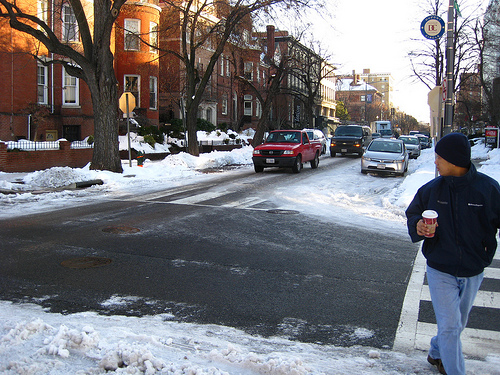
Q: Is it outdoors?
A: Yes, it is outdoors.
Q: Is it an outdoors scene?
A: Yes, it is outdoors.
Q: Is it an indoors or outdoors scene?
A: It is outdoors.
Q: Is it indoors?
A: No, it is outdoors.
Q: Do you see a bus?
A: No, there are no buses.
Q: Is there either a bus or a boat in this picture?
A: No, there are no buses or boats.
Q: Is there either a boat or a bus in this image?
A: No, there are no buses or boats.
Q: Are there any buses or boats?
A: No, there are no buses or boats.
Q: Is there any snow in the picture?
A: Yes, there is snow.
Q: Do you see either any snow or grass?
A: Yes, there is snow.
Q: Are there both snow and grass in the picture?
A: No, there is snow but no grass.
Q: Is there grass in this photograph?
A: No, there is no grass.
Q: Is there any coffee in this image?
A: Yes, there is coffee.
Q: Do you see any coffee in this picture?
A: Yes, there is coffee.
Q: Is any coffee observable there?
A: Yes, there is coffee.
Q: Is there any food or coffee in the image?
A: Yes, there is coffee.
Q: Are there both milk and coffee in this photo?
A: No, there is coffee but no milk.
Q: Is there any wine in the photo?
A: No, there is no wine.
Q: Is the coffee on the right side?
A: Yes, the coffee is on the right of the image.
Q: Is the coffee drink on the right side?
A: Yes, the coffee is on the right of the image.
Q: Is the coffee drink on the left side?
A: No, the coffee is on the right of the image.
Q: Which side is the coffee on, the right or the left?
A: The coffee is on the right of the image.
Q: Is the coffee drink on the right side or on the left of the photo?
A: The coffee is on the right of the image.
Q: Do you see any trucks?
A: Yes, there is a truck.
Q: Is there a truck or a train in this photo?
A: Yes, there is a truck.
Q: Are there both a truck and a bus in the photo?
A: No, there is a truck but no buses.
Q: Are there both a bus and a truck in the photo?
A: No, there is a truck but no buses.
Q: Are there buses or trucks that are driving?
A: Yes, the truck is driving.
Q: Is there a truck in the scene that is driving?
A: Yes, there is a truck that is driving.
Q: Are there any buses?
A: No, there are no buses.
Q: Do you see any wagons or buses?
A: No, there are no buses or wagons.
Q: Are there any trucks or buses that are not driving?
A: No, there is a truck but it is driving.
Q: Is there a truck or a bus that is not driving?
A: No, there is a truck but it is driving.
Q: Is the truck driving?
A: Yes, the truck is driving.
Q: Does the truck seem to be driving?
A: Yes, the truck is driving.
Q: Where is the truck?
A: The truck is on the snow.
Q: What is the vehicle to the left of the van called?
A: The vehicle is a truck.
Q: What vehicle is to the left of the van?
A: The vehicle is a truck.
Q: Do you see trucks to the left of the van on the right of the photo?
A: Yes, there is a truck to the left of the van.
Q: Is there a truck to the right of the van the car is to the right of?
A: No, the truck is to the left of the van.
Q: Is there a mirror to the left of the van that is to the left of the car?
A: No, there is a truck to the left of the van.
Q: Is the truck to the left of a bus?
A: No, the truck is to the left of the van.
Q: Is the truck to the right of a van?
A: No, the truck is to the left of a van.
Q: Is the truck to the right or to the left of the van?
A: The truck is to the left of the van.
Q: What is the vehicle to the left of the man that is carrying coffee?
A: The vehicle is a truck.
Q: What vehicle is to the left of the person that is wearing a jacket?
A: The vehicle is a truck.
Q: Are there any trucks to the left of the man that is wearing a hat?
A: Yes, there is a truck to the left of the man.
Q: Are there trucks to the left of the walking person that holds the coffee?
A: Yes, there is a truck to the left of the man.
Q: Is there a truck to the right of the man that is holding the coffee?
A: No, the truck is to the left of the man.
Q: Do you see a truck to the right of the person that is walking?
A: No, the truck is to the left of the man.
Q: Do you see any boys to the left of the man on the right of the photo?
A: No, there is a truck to the left of the man.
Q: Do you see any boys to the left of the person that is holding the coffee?
A: No, there is a truck to the left of the man.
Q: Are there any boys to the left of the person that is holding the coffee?
A: No, there is a truck to the left of the man.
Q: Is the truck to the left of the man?
A: Yes, the truck is to the left of the man.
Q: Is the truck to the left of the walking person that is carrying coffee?
A: Yes, the truck is to the left of the man.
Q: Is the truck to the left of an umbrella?
A: No, the truck is to the left of the man.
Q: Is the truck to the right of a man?
A: No, the truck is to the left of a man.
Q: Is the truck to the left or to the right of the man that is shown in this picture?
A: The truck is to the left of the man.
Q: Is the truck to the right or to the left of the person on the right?
A: The truck is to the left of the man.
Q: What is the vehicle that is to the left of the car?
A: The vehicle is a truck.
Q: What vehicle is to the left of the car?
A: The vehicle is a truck.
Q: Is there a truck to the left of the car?
A: Yes, there is a truck to the left of the car.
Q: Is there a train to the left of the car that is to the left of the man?
A: No, there is a truck to the left of the car.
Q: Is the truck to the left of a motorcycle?
A: No, the truck is to the left of the car.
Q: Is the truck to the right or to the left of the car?
A: The truck is to the left of the car.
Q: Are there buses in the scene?
A: No, there are no buses.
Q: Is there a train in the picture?
A: No, there are no trains.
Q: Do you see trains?
A: No, there are no trains.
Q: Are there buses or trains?
A: No, there are no trains or buses.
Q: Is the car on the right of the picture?
A: Yes, the car is on the right of the image.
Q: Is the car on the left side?
A: No, the car is on the right of the image.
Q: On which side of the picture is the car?
A: The car is on the right of the image.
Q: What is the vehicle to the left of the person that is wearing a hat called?
A: The vehicle is a car.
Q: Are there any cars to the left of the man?
A: Yes, there is a car to the left of the man.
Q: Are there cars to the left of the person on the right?
A: Yes, there is a car to the left of the man.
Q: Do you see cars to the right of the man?
A: No, the car is to the left of the man.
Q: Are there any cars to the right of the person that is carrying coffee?
A: No, the car is to the left of the man.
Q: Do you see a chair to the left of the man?
A: No, there is a car to the left of the man.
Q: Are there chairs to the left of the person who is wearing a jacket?
A: No, there is a car to the left of the man.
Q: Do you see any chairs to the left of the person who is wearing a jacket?
A: No, there is a car to the left of the man.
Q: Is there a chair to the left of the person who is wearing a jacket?
A: No, there is a car to the left of the man.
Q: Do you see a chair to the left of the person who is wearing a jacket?
A: No, there is a car to the left of the man.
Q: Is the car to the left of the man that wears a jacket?
A: Yes, the car is to the left of the man.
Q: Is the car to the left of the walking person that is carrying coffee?
A: Yes, the car is to the left of the man.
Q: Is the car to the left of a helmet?
A: No, the car is to the left of the man.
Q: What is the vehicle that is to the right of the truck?
A: The vehicle is a car.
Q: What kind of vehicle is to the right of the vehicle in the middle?
A: The vehicle is a car.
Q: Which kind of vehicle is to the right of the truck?
A: The vehicle is a car.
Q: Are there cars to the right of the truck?
A: Yes, there is a car to the right of the truck.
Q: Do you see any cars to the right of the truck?
A: Yes, there is a car to the right of the truck.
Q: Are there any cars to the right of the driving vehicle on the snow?
A: Yes, there is a car to the right of the truck.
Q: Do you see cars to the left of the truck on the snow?
A: No, the car is to the right of the truck.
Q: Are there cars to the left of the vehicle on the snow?
A: No, the car is to the right of the truck.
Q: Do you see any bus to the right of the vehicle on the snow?
A: No, there is a car to the right of the truck.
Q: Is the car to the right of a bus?
A: No, the car is to the right of a truck.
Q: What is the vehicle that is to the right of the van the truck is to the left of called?
A: The vehicle is a car.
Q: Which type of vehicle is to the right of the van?
A: The vehicle is a car.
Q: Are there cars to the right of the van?
A: Yes, there is a car to the right of the van.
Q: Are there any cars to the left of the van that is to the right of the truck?
A: No, the car is to the right of the van.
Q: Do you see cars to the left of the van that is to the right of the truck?
A: No, the car is to the right of the van.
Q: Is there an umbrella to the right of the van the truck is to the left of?
A: No, there is a car to the right of the van.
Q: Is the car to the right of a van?
A: Yes, the car is to the right of a van.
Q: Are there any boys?
A: No, there are no boys.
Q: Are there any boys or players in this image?
A: No, there are no boys or players.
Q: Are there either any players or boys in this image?
A: No, there are no boys or players.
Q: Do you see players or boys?
A: No, there are no boys or players.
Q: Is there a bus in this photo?
A: No, there are no buses.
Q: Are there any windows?
A: Yes, there are windows.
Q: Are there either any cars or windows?
A: Yes, there are windows.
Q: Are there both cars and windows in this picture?
A: Yes, there are both windows and a car.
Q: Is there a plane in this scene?
A: No, there are no airplanes.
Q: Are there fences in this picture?
A: Yes, there is a fence.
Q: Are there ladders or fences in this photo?
A: Yes, there is a fence.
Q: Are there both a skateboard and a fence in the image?
A: No, there is a fence but no skateboards.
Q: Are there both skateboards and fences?
A: No, there is a fence but no skateboards.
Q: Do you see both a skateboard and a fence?
A: No, there is a fence but no skateboards.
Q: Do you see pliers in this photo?
A: No, there are no pliers.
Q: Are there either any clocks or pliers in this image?
A: No, there are no pliers or clocks.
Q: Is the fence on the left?
A: Yes, the fence is on the left of the image.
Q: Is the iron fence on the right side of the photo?
A: No, the fence is on the left of the image.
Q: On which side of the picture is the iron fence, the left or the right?
A: The fence is on the left of the image.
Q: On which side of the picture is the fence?
A: The fence is on the left of the image.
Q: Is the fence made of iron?
A: Yes, the fence is made of iron.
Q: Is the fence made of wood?
A: No, the fence is made of iron.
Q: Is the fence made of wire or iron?
A: The fence is made of iron.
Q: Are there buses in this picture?
A: No, there are no buses.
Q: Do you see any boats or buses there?
A: No, there are no buses or boats.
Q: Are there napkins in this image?
A: No, there are no napkins.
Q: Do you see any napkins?
A: No, there are no napkins.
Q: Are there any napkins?
A: No, there are no napkins.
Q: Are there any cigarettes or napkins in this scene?
A: No, there are no napkins or cigarettes.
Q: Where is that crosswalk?
A: The crosswalk is on the snow.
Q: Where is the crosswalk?
A: The crosswalk is on the snow.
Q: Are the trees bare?
A: Yes, the trees are bare.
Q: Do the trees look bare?
A: Yes, the trees are bare.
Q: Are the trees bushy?
A: No, the trees are bare.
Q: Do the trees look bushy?
A: No, the trees are bare.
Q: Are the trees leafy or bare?
A: The trees are bare.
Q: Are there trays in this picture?
A: No, there are no trays.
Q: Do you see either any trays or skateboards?
A: No, there are no trays or skateboards.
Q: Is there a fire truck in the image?
A: No, there are no fire trucks.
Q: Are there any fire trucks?
A: No, there are no fire trucks.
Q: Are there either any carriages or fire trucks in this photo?
A: No, there are no fire trucks or carriages.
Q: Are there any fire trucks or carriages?
A: No, there are no fire trucks or carriages.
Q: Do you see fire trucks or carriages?
A: No, there are no fire trucks or carriages.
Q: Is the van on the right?
A: Yes, the van is on the right of the image.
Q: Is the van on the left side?
A: No, the van is on the right of the image.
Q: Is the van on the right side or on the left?
A: The van is on the right of the image.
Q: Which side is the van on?
A: The van is on the right of the image.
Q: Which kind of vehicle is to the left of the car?
A: The vehicle is a van.